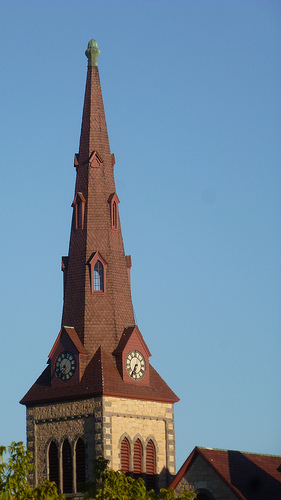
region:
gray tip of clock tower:
[77, 37, 102, 68]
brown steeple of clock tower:
[73, 62, 137, 328]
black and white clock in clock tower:
[121, 348, 148, 386]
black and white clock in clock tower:
[52, 352, 81, 382]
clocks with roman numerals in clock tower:
[27, 318, 160, 395]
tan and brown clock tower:
[23, 404, 175, 479]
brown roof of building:
[175, 441, 278, 493]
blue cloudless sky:
[130, 18, 272, 232]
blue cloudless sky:
[188, 303, 257, 437]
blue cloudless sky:
[14, 18, 52, 221]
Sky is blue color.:
[149, 200, 238, 320]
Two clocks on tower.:
[53, 352, 150, 386]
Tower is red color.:
[61, 271, 141, 342]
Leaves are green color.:
[4, 474, 44, 496]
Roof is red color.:
[211, 456, 272, 482]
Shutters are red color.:
[119, 439, 157, 471]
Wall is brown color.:
[37, 410, 163, 443]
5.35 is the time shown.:
[51, 349, 171, 388]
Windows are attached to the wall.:
[117, 433, 165, 490]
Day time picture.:
[11, 13, 272, 487]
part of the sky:
[171, 78, 219, 129]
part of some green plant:
[108, 480, 129, 498]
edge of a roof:
[177, 455, 191, 477]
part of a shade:
[232, 458, 259, 478]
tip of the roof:
[214, 446, 232, 452]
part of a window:
[124, 451, 147, 479]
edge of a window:
[114, 438, 126, 460]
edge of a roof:
[108, 388, 148, 403]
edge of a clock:
[119, 375, 141, 391]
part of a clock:
[120, 367, 140, 380]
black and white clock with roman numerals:
[117, 346, 150, 382]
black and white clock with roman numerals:
[50, 350, 79, 389]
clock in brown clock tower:
[114, 323, 152, 395]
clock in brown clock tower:
[45, 322, 87, 385]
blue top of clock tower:
[72, 29, 105, 79]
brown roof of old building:
[179, 438, 274, 492]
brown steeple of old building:
[66, 35, 132, 312]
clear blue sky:
[130, 5, 278, 335]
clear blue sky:
[6, 4, 41, 333]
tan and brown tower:
[29, 387, 184, 470]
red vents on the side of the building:
[102, 427, 176, 476]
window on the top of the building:
[89, 243, 119, 295]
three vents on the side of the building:
[39, 426, 96, 492]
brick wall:
[102, 402, 183, 429]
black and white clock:
[122, 341, 150, 383]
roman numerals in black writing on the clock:
[125, 344, 151, 383]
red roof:
[164, 444, 279, 498]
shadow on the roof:
[222, 441, 278, 497]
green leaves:
[0, 435, 218, 498]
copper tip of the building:
[78, 30, 113, 70]